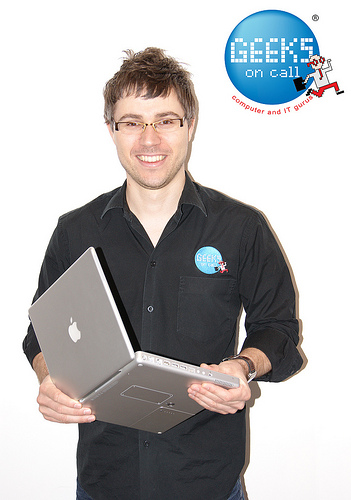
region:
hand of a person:
[194, 344, 264, 422]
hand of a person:
[37, 340, 120, 423]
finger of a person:
[188, 379, 244, 420]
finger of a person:
[23, 390, 95, 437]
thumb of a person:
[190, 347, 222, 376]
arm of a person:
[210, 250, 294, 365]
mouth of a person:
[132, 139, 176, 171]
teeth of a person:
[137, 147, 177, 170]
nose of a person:
[133, 126, 169, 150]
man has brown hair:
[98, 32, 193, 127]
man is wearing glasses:
[104, 103, 190, 135]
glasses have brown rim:
[103, 105, 184, 140]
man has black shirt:
[19, 194, 272, 492]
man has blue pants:
[219, 486, 266, 496]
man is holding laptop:
[32, 266, 221, 427]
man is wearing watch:
[219, 337, 256, 390]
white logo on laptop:
[68, 326, 80, 348]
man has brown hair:
[105, 52, 193, 105]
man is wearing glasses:
[109, 102, 189, 136]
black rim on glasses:
[103, 112, 195, 140]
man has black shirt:
[38, 195, 288, 480]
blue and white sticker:
[198, 225, 232, 280]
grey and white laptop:
[28, 271, 216, 437]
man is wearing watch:
[221, 358, 258, 386]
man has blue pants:
[232, 475, 259, 499]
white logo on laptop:
[58, 290, 86, 360]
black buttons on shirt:
[119, 255, 165, 348]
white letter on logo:
[228, 35, 248, 66]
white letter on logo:
[248, 33, 262, 66]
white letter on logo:
[264, 37, 281, 64]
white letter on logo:
[277, 34, 298, 68]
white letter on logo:
[298, 34, 316, 65]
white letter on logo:
[245, 68, 254, 77]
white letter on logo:
[253, 68, 266, 78]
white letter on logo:
[268, 65, 278, 79]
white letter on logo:
[278, 64, 289, 78]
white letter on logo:
[287, 64, 293, 81]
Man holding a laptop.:
[18, 37, 304, 499]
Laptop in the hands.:
[26, 245, 250, 438]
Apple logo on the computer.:
[64, 313, 83, 345]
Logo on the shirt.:
[193, 241, 235, 276]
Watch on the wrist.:
[220, 351, 258, 389]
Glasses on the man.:
[93, 44, 202, 192]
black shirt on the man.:
[24, 50, 304, 498]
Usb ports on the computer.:
[156, 354, 193, 372]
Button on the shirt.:
[145, 303, 155, 315]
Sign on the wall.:
[215, 7, 347, 126]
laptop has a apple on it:
[20, 245, 247, 438]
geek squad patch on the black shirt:
[16, 182, 303, 498]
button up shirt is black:
[22, 178, 299, 499]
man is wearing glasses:
[15, 60, 297, 497]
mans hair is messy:
[20, 46, 301, 496]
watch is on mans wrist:
[190, 351, 253, 418]